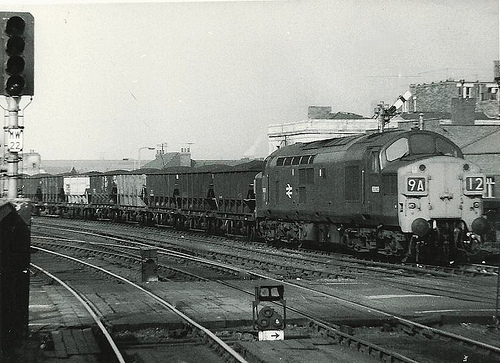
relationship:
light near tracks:
[0, 8, 53, 110] [58, 240, 340, 361]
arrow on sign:
[269, 332, 281, 338] [259, 330, 286, 344]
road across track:
[32, 276, 500, 326] [28, 214, 499, 362]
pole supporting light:
[4, 96, 24, 199] [0, 11, 35, 96]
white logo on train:
[280, 182, 292, 199] [14, 122, 496, 264]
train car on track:
[211, 168, 256, 239] [17, 217, 499, 362]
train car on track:
[144, 162, 230, 231] [17, 217, 499, 362]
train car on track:
[107, 169, 152, 217] [17, 217, 499, 362]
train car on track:
[59, 172, 110, 212] [17, 217, 499, 362]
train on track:
[14, 128, 488, 264] [28, 214, 499, 362]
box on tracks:
[129, 244, 186, 294] [59, 220, 400, 342]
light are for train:
[0, 11, 35, 97] [14, 122, 496, 264]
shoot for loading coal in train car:
[373, 90, 411, 131] [208, 149, 264, 239]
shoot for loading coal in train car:
[373, 90, 411, 131] [174, 159, 213, 228]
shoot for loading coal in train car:
[373, 90, 411, 131] [139, 165, 177, 225]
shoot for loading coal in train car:
[373, 90, 411, 131] [113, 170, 151, 220]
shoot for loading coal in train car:
[373, 90, 411, 131] [90, 171, 117, 218]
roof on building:
[150, 149, 177, 168] [136, 145, 201, 170]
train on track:
[14, 122, 496, 264] [28, 214, 499, 362]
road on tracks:
[40, 280, 463, 320] [39, 215, 346, 306]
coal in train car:
[104, 164, 266, 171] [211, 168, 256, 239]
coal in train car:
[104, 164, 266, 171] [174, 171, 214, 229]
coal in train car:
[104, 164, 266, 171] [144, 171, 179, 227]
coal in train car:
[104, 164, 266, 171] [115, 171, 147, 222]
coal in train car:
[104, 164, 266, 171] [89, 172, 115, 219]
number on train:
[458, 174, 486, 197] [14, 122, 496, 264]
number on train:
[402, 173, 417, 201] [14, 122, 496, 264]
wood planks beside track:
[43, 323, 105, 360] [28, 214, 499, 362]